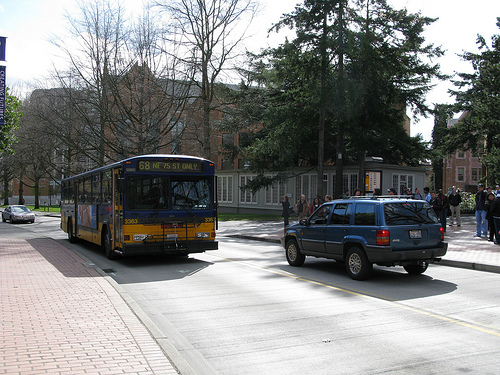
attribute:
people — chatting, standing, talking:
[421, 176, 500, 242]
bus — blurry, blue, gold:
[60, 140, 229, 262]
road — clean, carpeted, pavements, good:
[152, 270, 409, 343]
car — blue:
[285, 201, 455, 282]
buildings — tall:
[37, 85, 482, 186]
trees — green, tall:
[214, 49, 497, 142]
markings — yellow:
[270, 289, 496, 338]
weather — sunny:
[25, 11, 262, 67]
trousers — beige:
[450, 207, 463, 230]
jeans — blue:
[473, 213, 489, 241]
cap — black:
[477, 179, 485, 190]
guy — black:
[429, 187, 452, 229]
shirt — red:
[440, 197, 450, 202]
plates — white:
[409, 229, 429, 243]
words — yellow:
[134, 158, 206, 177]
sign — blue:
[71, 204, 104, 230]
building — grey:
[221, 167, 433, 202]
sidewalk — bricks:
[15, 248, 102, 375]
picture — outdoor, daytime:
[17, 11, 484, 321]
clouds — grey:
[20, 12, 49, 40]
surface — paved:
[174, 301, 487, 361]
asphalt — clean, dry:
[68, 87, 278, 241]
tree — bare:
[73, 35, 221, 146]